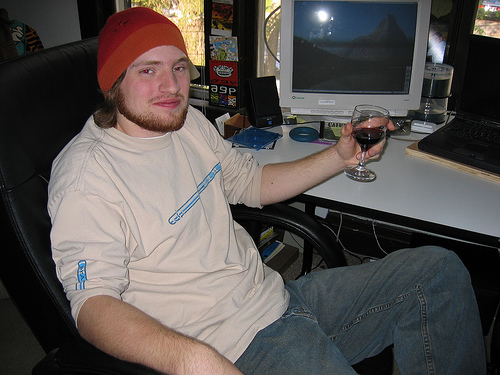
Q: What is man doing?
A: Drinking wine.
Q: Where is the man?
A: Sitting in chair.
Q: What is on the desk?
A: Computer monitor.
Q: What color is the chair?
A: Black.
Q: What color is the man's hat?
A: Orange.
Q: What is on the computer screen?
A: Mountain scene.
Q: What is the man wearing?
A: Jeans and a long sleeve shirt.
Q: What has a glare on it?
A: A white computer monitor.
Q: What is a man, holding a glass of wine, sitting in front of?
A: A white computer monitor on a table.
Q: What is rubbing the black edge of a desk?
A: The knee of a man.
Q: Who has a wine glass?
A: A man sitting on a chair.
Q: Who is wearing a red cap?
A: A man holding a wine glass.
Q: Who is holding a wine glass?
A: A man wearing a red cap.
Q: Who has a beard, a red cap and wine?
A: A man sitting next to a computer.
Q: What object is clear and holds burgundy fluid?
A: A glass of wine in a person's hand.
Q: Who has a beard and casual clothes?
A: A male, wearing a red stocking hat.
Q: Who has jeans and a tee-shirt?
A: A man with facial hair.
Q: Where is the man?
A: In front of a computer.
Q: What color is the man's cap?
A: Orange.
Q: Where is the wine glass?
A: In the man's hand.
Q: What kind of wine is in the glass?
A: Red.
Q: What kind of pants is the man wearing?
A: Jeans.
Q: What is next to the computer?
A: Cd cases.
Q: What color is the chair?
A: Black.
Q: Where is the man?
A: In a chair.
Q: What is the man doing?
A: Drinking wine.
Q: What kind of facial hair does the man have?
A: Beard and mustache.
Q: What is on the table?
A: Computer monitor.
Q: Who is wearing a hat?
A: The man.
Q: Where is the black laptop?
A: To the right.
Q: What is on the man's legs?
A: Jeans.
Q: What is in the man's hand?
A: A glass.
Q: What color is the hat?
A: Orange.